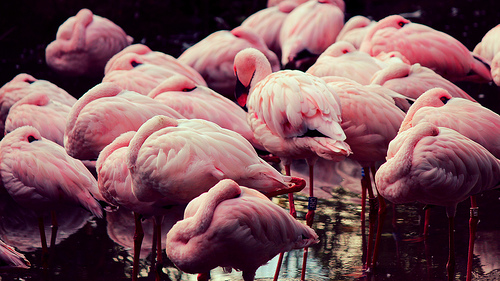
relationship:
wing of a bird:
[251, 80, 305, 125] [232, 47, 355, 280]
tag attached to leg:
[306, 196, 319, 213] [306, 165, 316, 223]